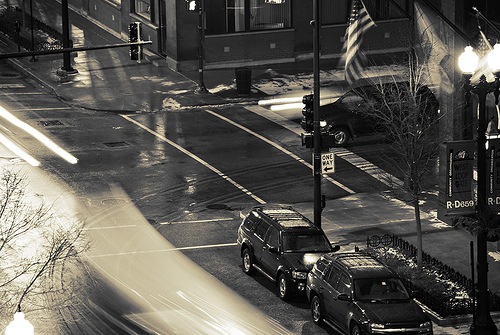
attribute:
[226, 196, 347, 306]
vehicle — parked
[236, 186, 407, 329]
cars — parked, driving, black, big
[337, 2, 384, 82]
flag — american, flying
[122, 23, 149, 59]
light — traffic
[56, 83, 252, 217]
road — wet, dark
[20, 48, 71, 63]
pole — black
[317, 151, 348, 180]
sign — black, white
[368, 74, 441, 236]
tree — bare